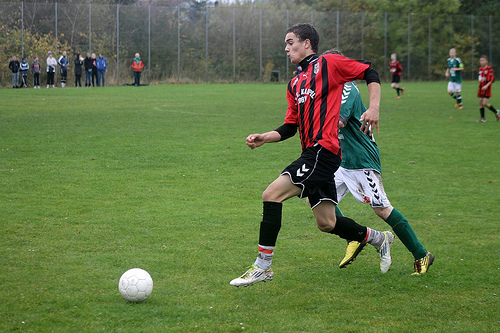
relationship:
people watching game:
[22, 43, 116, 93] [50, 51, 498, 329]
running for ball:
[219, 112, 441, 329] [99, 270, 163, 299]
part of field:
[185, 87, 279, 192] [171, 81, 240, 178]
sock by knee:
[396, 206, 432, 272] [376, 199, 388, 222]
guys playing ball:
[259, 40, 417, 274] [117, 266, 156, 301]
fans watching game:
[87, 43, 153, 79] [50, 51, 498, 329]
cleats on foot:
[367, 224, 434, 286] [412, 249, 432, 284]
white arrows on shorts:
[290, 164, 313, 186] [293, 146, 343, 209]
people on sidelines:
[22, 43, 116, 93] [119, 77, 263, 87]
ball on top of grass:
[99, 270, 163, 299] [24, 124, 173, 226]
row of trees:
[166, 25, 291, 68] [182, 21, 238, 68]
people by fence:
[22, 43, 116, 93] [154, 11, 243, 94]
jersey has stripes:
[295, 72, 337, 150] [321, 61, 329, 146]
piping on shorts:
[300, 150, 319, 188] [293, 146, 343, 209]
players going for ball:
[247, 19, 482, 305] [99, 270, 163, 299]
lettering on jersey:
[294, 89, 317, 109] [295, 72, 337, 150]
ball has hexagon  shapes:
[99, 270, 163, 299] [137, 275, 150, 294]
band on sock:
[255, 244, 277, 256] [339, 214, 371, 252]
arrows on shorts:
[357, 166, 387, 202] [346, 166, 399, 222]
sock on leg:
[339, 214, 371, 252] [243, 162, 308, 297]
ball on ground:
[99, 270, 163, 299] [56, 255, 142, 329]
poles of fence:
[173, 14, 189, 85] [154, 11, 243, 94]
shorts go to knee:
[293, 146, 343, 209] [265, 188, 282, 209]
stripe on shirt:
[354, 119, 390, 155] [349, 79, 381, 167]